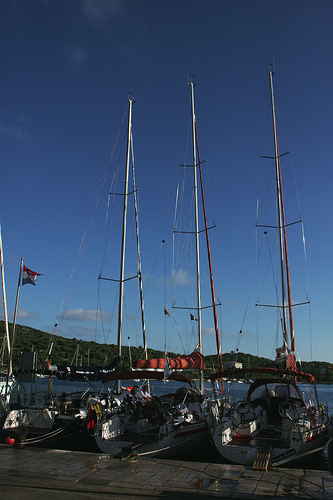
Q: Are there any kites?
A: No, there are no kites.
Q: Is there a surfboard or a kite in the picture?
A: No, there are no kites or surfboards.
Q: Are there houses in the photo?
A: No, there are no houses.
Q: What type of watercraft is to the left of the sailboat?
A: The watercraft is boats.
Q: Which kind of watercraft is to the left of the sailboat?
A: The watercraft is boats.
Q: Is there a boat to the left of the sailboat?
A: Yes, there are boats to the left of the sailboat.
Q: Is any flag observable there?
A: Yes, there is a flag.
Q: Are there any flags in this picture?
A: Yes, there is a flag.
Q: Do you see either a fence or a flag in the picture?
A: Yes, there is a flag.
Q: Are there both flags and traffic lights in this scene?
A: No, there is a flag but no traffic lights.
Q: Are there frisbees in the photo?
A: No, there are no frisbees.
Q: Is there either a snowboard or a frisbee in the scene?
A: No, there are no frisbees or snowboards.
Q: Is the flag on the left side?
A: Yes, the flag is on the left of the image.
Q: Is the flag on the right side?
A: No, the flag is on the left of the image.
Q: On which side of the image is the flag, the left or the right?
A: The flag is on the left of the image.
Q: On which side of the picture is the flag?
A: The flag is on the left of the image.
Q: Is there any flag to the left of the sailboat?
A: Yes, there is a flag to the left of the sailboat.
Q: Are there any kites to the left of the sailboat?
A: No, there is a flag to the left of the sailboat.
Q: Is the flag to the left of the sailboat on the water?
A: Yes, the flag is to the left of the sailboat.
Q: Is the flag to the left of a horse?
A: No, the flag is to the left of the sailboat.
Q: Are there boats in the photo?
A: Yes, there is a boat.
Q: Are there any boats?
A: Yes, there is a boat.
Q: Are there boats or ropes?
A: Yes, there is a boat.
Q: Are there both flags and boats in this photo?
A: Yes, there are both a boat and a flag.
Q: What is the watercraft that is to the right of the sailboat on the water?
A: The watercraft is a boat.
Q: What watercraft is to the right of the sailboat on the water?
A: The watercraft is a boat.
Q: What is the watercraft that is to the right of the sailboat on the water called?
A: The watercraft is a boat.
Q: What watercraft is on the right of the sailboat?
A: The watercraft is a boat.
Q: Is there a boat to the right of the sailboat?
A: Yes, there is a boat to the right of the sailboat.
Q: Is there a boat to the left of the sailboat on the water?
A: No, the boat is to the right of the sailboat.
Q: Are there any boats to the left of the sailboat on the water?
A: No, the boat is to the right of the sailboat.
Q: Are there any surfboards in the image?
A: No, there are no surfboards.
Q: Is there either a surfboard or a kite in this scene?
A: No, there are no surfboards or kites.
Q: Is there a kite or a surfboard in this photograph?
A: No, there are no surfboards or kites.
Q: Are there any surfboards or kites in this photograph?
A: No, there are no surfboards or kites.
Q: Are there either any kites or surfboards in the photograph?
A: No, there are no surfboards or kites.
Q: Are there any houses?
A: No, there are no houses.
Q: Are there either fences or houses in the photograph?
A: No, there are no houses or fences.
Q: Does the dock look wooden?
A: Yes, the dock is wooden.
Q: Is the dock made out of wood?
A: Yes, the dock is made of wood.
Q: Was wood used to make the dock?
A: Yes, the dock is made of wood.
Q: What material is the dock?
A: The dock is made of wood.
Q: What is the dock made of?
A: The dock is made of wood.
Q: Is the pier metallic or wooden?
A: The pier is wooden.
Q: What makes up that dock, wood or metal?
A: The dock is made of wood.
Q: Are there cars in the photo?
A: No, there are no cars.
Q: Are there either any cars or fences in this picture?
A: No, there are no cars or fences.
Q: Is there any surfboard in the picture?
A: No, there are no surfboards.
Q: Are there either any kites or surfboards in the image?
A: No, there are no surfboards or kites.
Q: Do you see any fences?
A: No, there are no fences.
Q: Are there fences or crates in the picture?
A: No, there are no fences or crates.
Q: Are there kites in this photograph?
A: No, there are no kites.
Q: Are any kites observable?
A: No, there are no kites.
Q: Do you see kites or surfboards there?
A: No, there are no kites or surfboards.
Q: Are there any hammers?
A: No, there are no hammers.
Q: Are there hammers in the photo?
A: No, there are no hammers.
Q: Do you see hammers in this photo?
A: No, there are no hammers.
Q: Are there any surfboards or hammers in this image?
A: No, there are no hammers or surfboards.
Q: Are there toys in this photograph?
A: No, there are no toys.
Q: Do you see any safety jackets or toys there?
A: No, there are no toys or safety jackets.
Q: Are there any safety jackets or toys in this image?
A: No, there are no toys or safety jackets.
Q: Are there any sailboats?
A: Yes, there is a sailboat.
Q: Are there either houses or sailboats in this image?
A: Yes, there is a sailboat.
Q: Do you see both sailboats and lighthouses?
A: No, there is a sailboat but no lighthouses.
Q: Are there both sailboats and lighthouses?
A: No, there is a sailboat but no lighthouses.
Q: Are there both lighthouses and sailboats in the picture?
A: No, there is a sailboat but no lighthouses.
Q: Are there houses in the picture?
A: No, there are no houses.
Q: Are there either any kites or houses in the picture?
A: No, there are no houses or kites.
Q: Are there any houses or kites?
A: No, there are no houses or kites.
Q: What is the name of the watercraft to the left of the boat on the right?
A: The watercraft is a sailboat.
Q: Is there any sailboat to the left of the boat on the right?
A: Yes, there is a sailboat to the left of the boat.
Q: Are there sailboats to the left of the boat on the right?
A: Yes, there is a sailboat to the left of the boat.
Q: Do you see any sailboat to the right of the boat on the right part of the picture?
A: No, the sailboat is to the left of the boat.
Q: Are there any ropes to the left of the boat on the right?
A: No, there is a sailboat to the left of the boat.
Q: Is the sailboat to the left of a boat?
A: Yes, the sailboat is to the left of a boat.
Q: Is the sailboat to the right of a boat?
A: No, the sailboat is to the left of a boat.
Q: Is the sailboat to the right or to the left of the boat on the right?
A: The sailboat is to the left of the boat.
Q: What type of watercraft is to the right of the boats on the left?
A: The watercraft is a sailboat.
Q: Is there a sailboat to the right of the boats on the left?
A: Yes, there is a sailboat to the right of the boats.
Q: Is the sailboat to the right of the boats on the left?
A: Yes, the sailboat is to the right of the boats.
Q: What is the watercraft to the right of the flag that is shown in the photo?
A: The watercraft is a sailboat.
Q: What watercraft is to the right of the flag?
A: The watercraft is a sailboat.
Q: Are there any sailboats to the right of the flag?
A: Yes, there is a sailboat to the right of the flag.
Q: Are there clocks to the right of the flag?
A: No, there is a sailboat to the right of the flag.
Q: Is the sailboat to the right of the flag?
A: Yes, the sailboat is to the right of the flag.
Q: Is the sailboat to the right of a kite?
A: No, the sailboat is to the right of the flag.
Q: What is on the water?
A: The sailboat is on the water.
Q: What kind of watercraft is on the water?
A: The watercraft is a sailboat.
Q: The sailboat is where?
A: The sailboat is on the water.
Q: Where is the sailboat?
A: The sailboat is on the water.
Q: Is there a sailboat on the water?
A: Yes, there is a sailboat on the water.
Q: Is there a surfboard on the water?
A: No, there is a sailboat on the water.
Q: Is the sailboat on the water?
A: Yes, the sailboat is on the water.